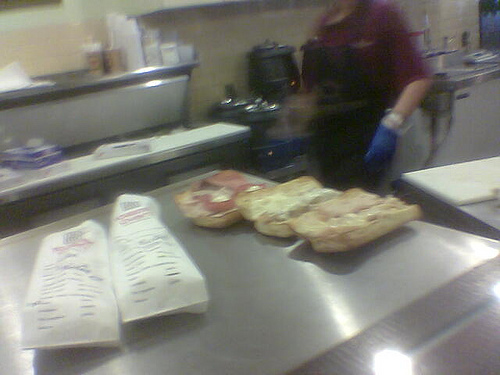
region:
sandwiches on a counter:
[122, 102, 465, 321]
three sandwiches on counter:
[162, 155, 418, 283]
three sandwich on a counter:
[154, 131, 433, 284]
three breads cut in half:
[164, 125, 401, 327]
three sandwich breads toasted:
[157, 117, 408, 311]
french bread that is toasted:
[134, 93, 491, 349]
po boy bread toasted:
[172, 136, 439, 293]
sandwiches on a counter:
[184, 144, 435, 279]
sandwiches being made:
[141, 135, 485, 270]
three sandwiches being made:
[169, 107, 428, 264]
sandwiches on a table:
[126, 119, 432, 290]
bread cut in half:
[189, 149, 418, 294]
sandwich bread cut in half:
[161, 148, 411, 265]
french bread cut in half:
[159, 138, 416, 288]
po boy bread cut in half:
[174, 133, 459, 319]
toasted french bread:
[192, 129, 408, 264]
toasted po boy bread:
[155, 124, 477, 334]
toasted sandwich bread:
[148, 155, 409, 275]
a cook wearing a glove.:
[269, 8, 455, 240]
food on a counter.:
[155, 152, 433, 280]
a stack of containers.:
[120, 16, 143, 77]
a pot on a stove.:
[222, 26, 307, 103]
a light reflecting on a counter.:
[367, 331, 437, 372]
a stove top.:
[198, 78, 293, 146]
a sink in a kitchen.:
[416, 31, 493, 132]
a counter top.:
[0, 62, 196, 172]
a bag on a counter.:
[103, 185, 213, 338]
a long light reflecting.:
[283, 249, 366, 346]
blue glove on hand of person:
[357, 122, 406, 176]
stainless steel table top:
[217, 267, 301, 345]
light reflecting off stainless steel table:
[340, 302, 436, 374]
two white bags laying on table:
[27, 180, 218, 357]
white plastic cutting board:
[408, 147, 498, 210]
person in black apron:
[282, 10, 428, 188]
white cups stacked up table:
[94, 15, 207, 78]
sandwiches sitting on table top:
[178, 150, 423, 274]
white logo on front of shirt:
[348, 37, 384, 55]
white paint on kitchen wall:
[456, 99, 498, 147]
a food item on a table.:
[277, 177, 431, 269]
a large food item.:
[234, 161, 341, 241]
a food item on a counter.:
[162, 158, 269, 240]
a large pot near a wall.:
[230, 29, 302, 103]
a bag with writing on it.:
[10, 208, 120, 368]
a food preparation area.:
[0, 108, 256, 213]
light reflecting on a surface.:
[375, 328, 440, 374]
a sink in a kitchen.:
[403, 48, 481, 99]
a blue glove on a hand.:
[329, 106, 413, 177]